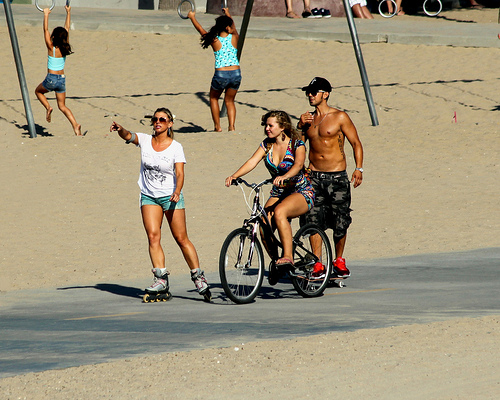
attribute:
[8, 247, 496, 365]
walkway — paved, concrete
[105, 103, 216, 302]
woman — pointing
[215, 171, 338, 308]
bicycle — black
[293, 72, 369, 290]
man — young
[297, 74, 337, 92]
cap — black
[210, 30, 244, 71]
top — blue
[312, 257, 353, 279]
sneakers — black, red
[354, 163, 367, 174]
watch — silver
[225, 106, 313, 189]
hair — long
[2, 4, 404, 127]
girl — young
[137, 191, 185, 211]
shorts — blue